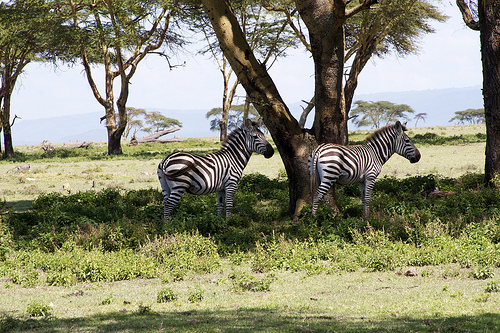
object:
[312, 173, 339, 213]
leg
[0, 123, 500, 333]
grass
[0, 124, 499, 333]
ground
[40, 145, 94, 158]
bush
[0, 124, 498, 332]
african plain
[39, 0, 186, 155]
tall tree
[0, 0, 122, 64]
green leaves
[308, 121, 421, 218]
zebra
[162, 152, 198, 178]
tail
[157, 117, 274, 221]
zebra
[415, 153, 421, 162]
nose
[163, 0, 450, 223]
tree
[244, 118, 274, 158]
head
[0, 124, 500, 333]
plain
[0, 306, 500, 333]
shade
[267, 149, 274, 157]
nose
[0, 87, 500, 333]
wild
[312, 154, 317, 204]
tail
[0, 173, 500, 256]
shade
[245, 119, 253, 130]
ear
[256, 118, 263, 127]
ear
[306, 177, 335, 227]
part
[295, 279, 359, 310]
part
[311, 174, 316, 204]
part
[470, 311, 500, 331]
part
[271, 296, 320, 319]
part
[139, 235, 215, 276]
part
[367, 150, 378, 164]
part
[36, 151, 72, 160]
part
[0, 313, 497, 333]
edge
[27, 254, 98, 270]
part